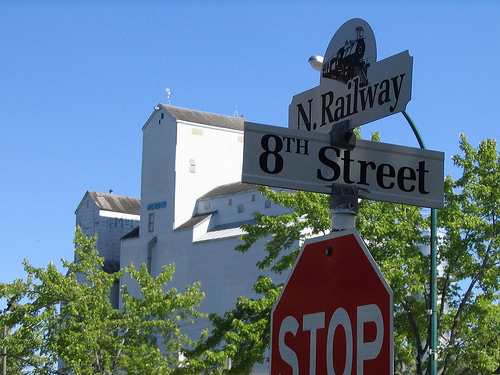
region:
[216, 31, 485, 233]
street signs are white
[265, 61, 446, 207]
black letters on sign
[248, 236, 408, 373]
the sign is red and white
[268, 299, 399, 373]
white letters on sign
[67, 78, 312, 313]
the building is white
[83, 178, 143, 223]
the roof is black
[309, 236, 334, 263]
metal piece on sign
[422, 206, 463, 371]
the street pole is green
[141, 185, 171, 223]
blue label on building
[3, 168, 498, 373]
trees behind the sign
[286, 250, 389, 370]
STOP written in white on the sign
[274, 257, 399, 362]
stop sign is octagon shaped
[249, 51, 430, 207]
two white street sign above stop sign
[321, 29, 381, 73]
picture of a train on the sign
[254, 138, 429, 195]
8th Street written of street sign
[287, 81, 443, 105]
N. Railway is written on sign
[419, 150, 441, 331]
street light pole is green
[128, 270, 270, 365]
tree next to stop sign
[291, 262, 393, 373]
stop sign is red and white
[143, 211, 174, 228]
window under the sign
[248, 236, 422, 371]
A red stop sign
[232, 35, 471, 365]
The stop sign at N. Railway and 8th Street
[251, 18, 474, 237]
White street signs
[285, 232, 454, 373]
a red stop sign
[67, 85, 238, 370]
A large white factory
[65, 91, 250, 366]
A large white building behind the trees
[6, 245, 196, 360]
Green trees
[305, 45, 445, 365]
Green lamppost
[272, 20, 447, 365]
Street sign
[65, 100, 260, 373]
A white building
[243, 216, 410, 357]
A red stop sign.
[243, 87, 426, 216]
Black and white signs above the stop sign.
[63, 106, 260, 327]
A white tall building.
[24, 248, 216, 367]
Trees in front of the building.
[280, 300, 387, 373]
The letters on the sign is white.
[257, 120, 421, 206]
The sign is black and white.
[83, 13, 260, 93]
The sky is blue and clear.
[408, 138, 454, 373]
The light pole is green.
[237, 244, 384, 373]
The sign is red and white.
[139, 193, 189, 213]
Blue writing on the building.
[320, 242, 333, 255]
Screw on Stop sign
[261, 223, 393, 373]
Stop sign is red and white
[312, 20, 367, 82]
Train painted on traffic sign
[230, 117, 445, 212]
Traffic sign is black and white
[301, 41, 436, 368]
Green light post by tree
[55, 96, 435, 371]
Large white building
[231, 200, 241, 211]
Small window on white building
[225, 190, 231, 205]
Small window on white building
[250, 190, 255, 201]
Small window on white building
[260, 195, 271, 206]
Small window on white building